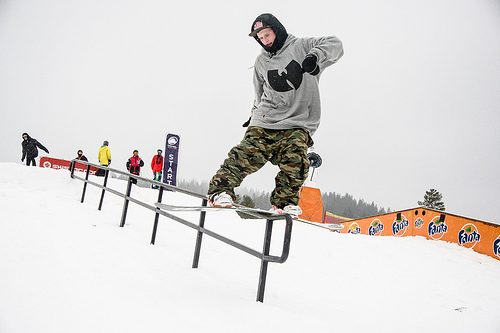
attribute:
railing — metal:
[63, 157, 215, 243]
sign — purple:
[165, 130, 179, 191]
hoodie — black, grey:
[242, 41, 332, 142]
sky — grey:
[354, 8, 484, 61]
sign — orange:
[382, 211, 472, 245]